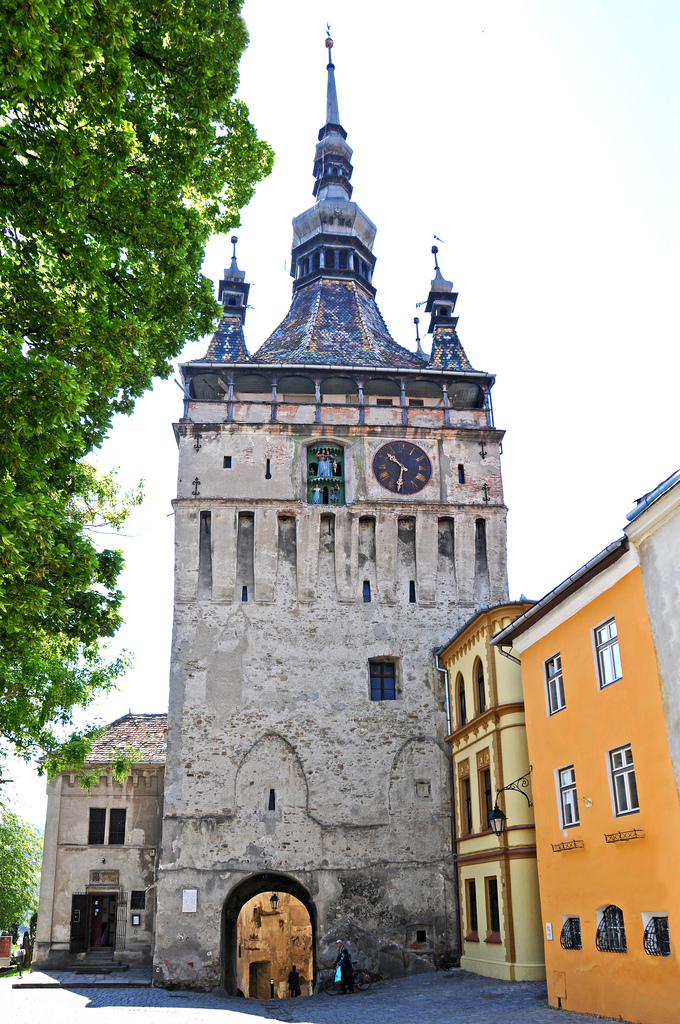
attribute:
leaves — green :
[15, 7, 284, 767]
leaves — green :
[43, 593, 82, 678]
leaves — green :
[4, 702, 149, 784]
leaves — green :
[10, 266, 221, 383]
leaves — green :
[36, 142, 99, 282]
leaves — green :
[33, 43, 167, 166]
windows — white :
[540, 615, 643, 842]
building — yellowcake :
[445, 608, 540, 978]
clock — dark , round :
[369, 435, 439, 494]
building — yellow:
[431, 628, 601, 986]